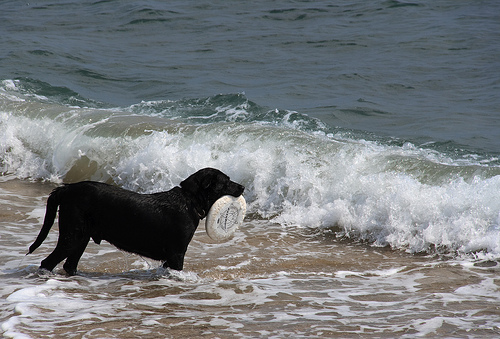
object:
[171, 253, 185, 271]
leg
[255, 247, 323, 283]
water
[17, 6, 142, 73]
water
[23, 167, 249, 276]
dog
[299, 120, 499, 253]
wave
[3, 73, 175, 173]
wave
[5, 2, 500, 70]
water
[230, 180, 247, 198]
snout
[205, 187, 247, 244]
frisbee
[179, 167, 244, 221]
head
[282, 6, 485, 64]
water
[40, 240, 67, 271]
leg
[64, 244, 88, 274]
leg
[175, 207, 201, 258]
chest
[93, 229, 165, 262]
stomach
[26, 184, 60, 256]
tail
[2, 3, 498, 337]
ocean